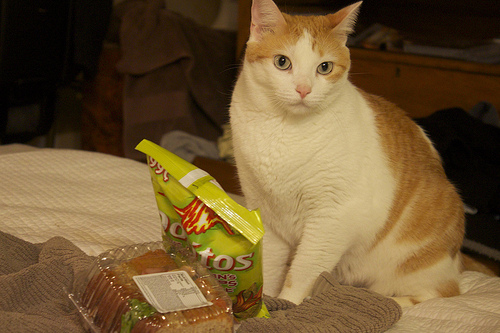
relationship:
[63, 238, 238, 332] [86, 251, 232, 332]
box of tomatoes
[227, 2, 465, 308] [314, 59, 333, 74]
cat has right eye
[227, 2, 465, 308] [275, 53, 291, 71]
cat has left eye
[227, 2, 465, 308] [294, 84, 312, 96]
cat has nose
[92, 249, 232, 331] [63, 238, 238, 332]
sandwich in box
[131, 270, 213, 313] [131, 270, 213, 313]
sticker with sticker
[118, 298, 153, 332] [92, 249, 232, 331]
lettuce on sandwich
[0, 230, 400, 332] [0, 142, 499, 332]
towel on bed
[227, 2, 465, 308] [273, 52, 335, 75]
cat has eyes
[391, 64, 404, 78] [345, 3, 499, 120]
key hole on chest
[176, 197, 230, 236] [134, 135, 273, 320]
flame on bag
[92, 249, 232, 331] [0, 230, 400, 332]
sandwich on towel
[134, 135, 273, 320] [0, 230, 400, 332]
bag on towel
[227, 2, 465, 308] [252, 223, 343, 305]
cat has front paws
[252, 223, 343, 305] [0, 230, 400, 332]
front paws are on towel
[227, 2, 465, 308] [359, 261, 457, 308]
cat has hind legs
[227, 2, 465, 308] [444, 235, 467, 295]
cat has tail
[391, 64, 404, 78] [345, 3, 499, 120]
key hole to chest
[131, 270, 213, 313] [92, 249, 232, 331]
sticker for sandwich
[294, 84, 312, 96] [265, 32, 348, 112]
nose on face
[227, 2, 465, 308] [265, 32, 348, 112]
cat has face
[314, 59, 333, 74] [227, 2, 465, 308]
right eye of cat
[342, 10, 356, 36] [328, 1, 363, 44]
hair in ear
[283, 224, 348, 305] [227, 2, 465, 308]
leg of cat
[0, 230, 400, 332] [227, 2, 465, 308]
towel under cat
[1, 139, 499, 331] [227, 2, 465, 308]
blanket under cat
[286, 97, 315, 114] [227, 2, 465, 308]
lips of cat